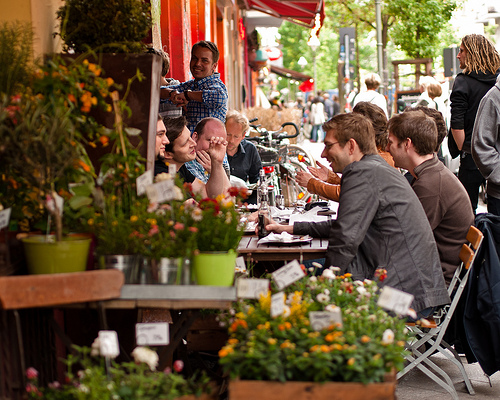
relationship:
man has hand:
[164, 117, 238, 202] [209, 136, 227, 160]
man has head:
[162, 37, 229, 179] [188, 38, 218, 79]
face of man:
[188, 45, 213, 80] [162, 37, 229, 179]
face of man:
[172, 125, 198, 164] [164, 117, 231, 200]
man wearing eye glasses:
[251, 111, 451, 315] [323, 138, 344, 148]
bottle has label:
[258, 189, 271, 237] [256, 211, 265, 235]